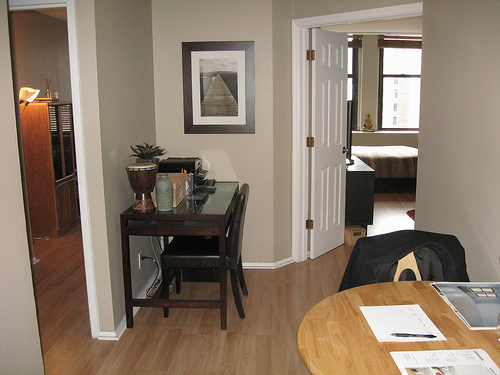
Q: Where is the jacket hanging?
A: Back of chair.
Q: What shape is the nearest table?
A: Round.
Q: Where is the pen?
A: On the table.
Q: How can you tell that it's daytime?
A: Sunlight in window.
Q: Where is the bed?
A: By the windows.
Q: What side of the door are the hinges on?
A: Left.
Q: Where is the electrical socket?
A: Under the desk.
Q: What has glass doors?
A: Wall unit.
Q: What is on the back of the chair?
A: Black jacket.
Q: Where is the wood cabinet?
A: In hallway.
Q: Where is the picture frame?
A: Hanging on wall.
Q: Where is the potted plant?
A: On dark wood desk.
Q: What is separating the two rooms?
A: White door.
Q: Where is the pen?
A: On light wood table?.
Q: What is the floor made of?
A: Wood.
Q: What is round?
A: Table.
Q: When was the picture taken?
A: Daytime.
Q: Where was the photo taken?
A: In a house.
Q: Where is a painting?
A: On the wall.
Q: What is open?
A: A door.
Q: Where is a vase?
A: On the table.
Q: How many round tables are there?
A: One.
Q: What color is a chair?
A: Brown.